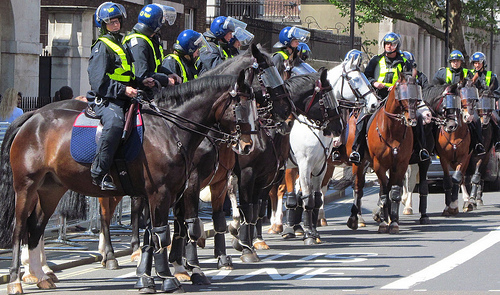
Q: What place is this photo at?
A: It is at the street.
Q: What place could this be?
A: It is a street.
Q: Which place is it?
A: It is a street.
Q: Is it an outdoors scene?
A: Yes, it is outdoors.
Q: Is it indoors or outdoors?
A: It is outdoors.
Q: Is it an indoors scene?
A: No, it is outdoors.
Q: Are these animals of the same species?
A: Yes, all the animals are horses.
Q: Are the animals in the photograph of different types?
A: No, all the animals are horses.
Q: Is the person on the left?
A: Yes, the person is on the left of the image.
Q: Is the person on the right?
A: No, the person is on the left of the image.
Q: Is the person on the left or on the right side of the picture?
A: The person is on the left of the image.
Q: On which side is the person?
A: The person is on the left of the image.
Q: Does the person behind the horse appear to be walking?
A: Yes, the person is walking.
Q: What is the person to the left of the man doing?
A: The person is walking.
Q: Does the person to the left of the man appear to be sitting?
A: No, the person is walking.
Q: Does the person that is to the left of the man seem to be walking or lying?
A: The person is walking.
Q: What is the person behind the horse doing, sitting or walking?
A: The person is walking.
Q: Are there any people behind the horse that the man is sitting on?
A: Yes, there is a person behind the horse.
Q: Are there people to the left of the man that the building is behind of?
A: Yes, there is a person to the left of the man.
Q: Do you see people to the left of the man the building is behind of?
A: Yes, there is a person to the left of the man.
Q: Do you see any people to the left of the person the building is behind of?
A: Yes, there is a person to the left of the man.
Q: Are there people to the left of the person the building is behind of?
A: Yes, there is a person to the left of the man.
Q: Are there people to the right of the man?
A: No, the person is to the left of the man.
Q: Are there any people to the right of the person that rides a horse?
A: No, the person is to the left of the man.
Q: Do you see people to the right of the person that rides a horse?
A: No, the person is to the left of the man.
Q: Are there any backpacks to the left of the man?
A: No, there is a person to the left of the man.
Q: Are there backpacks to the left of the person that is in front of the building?
A: No, there is a person to the left of the man.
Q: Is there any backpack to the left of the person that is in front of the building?
A: No, there is a person to the left of the man.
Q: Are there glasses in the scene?
A: No, there are no glasses.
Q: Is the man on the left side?
A: Yes, the man is on the left of the image.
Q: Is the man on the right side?
A: No, the man is on the left of the image.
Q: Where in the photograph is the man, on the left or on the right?
A: The man is on the left of the image.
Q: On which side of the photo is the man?
A: The man is on the left of the image.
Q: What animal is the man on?
A: The man is on the horse.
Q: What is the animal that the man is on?
A: The animal is a horse.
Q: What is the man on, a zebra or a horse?
A: The man is on a horse.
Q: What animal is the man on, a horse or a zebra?
A: The man is on a horse.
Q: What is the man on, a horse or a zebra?
A: The man is on a horse.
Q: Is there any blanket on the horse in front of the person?
A: No, there is a man on the horse.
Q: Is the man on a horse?
A: Yes, the man is on a horse.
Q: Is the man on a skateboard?
A: No, the man is on a horse.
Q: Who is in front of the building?
A: The man is in front of the building.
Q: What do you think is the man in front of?
A: The man is in front of the building.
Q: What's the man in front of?
A: The man is in front of the building.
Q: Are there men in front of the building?
A: Yes, there is a man in front of the building.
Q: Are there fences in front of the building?
A: No, there is a man in front of the building.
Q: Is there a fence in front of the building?
A: No, there is a man in front of the building.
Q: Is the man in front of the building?
A: Yes, the man is in front of the building.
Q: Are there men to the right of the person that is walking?
A: Yes, there is a man to the right of the person.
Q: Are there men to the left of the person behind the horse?
A: No, the man is to the right of the person.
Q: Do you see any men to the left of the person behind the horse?
A: No, the man is to the right of the person.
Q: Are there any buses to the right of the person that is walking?
A: No, there is a man to the right of the person.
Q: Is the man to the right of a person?
A: Yes, the man is to the right of a person.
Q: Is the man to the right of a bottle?
A: No, the man is to the right of a person.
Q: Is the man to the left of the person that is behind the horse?
A: No, the man is to the right of the person.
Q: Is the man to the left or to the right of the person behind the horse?
A: The man is to the right of the person.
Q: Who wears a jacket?
A: The man wears a jacket.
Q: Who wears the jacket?
A: The man wears a jacket.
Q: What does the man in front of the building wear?
A: The man wears a jacket.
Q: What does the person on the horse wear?
A: The man wears a jacket.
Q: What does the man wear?
A: The man wears a jacket.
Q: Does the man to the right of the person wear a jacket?
A: Yes, the man wears a jacket.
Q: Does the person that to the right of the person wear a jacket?
A: Yes, the man wears a jacket.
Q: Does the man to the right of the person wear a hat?
A: No, the man wears a jacket.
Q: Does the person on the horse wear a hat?
A: No, the man wears a jacket.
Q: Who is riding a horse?
A: The man is riding a horse.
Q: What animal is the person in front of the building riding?
A: The man is riding a horse.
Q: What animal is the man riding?
A: The man is riding a horse.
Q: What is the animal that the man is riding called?
A: The animal is a horse.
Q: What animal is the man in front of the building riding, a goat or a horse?
A: The man is riding a horse.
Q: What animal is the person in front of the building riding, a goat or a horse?
A: The man is riding a horse.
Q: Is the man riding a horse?
A: Yes, the man is riding a horse.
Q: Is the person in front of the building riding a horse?
A: Yes, the man is riding a horse.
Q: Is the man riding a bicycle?
A: No, the man is riding a horse.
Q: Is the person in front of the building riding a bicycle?
A: No, the man is riding a horse.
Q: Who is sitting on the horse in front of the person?
A: The man is sitting on the horse.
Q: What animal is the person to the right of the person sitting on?
A: The man is sitting on the horse.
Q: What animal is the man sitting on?
A: The man is sitting on the horse.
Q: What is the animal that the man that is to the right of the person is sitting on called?
A: The animal is a horse.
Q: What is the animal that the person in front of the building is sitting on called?
A: The animal is a horse.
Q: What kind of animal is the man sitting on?
A: The man is sitting on the horse.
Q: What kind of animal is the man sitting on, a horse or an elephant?
A: The man is sitting on a horse.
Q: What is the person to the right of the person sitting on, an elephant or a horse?
A: The man is sitting on a horse.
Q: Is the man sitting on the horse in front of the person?
A: Yes, the man is sitting on the horse.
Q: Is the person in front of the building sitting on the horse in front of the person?
A: Yes, the man is sitting on the horse.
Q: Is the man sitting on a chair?
A: No, the man is sitting on the horse.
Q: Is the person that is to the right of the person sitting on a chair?
A: No, the man is sitting on the horse.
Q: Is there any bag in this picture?
A: No, there are no bags.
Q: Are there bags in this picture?
A: No, there are no bags.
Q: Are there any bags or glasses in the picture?
A: No, there are no bags or glasses.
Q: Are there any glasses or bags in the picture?
A: No, there are no bags or glasses.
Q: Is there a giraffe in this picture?
A: No, there are no giraffes.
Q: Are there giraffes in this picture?
A: No, there are no giraffes.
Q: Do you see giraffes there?
A: No, there are no giraffes.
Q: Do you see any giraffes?
A: No, there are no giraffes.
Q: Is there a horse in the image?
A: Yes, there is a horse.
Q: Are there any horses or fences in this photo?
A: Yes, there is a horse.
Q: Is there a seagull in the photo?
A: No, there are no seagulls.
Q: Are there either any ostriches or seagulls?
A: No, there are no seagulls or ostriches.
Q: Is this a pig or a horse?
A: This is a horse.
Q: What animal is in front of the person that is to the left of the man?
A: The horse is in front of the person.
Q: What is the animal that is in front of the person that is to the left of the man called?
A: The animal is a horse.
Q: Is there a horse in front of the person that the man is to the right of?
A: Yes, there is a horse in front of the person.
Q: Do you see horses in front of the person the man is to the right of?
A: Yes, there is a horse in front of the person.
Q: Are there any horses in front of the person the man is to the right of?
A: Yes, there is a horse in front of the person.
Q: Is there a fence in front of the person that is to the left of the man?
A: No, there is a horse in front of the person.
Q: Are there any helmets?
A: Yes, there is a helmet.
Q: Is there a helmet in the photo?
A: Yes, there is a helmet.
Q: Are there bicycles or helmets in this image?
A: Yes, there is a helmet.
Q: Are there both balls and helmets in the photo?
A: No, there is a helmet but no balls.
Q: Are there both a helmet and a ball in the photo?
A: No, there is a helmet but no balls.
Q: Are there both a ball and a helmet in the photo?
A: No, there is a helmet but no balls.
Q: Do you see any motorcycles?
A: No, there are no motorcycles.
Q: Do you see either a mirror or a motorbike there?
A: No, there are no motorcycles or mirrors.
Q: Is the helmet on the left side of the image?
A: Yes, the helmet is on the left of the image.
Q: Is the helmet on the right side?
A: No, the helmet is on the left of the image.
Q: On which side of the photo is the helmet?
A: The helmet is on the left of the image.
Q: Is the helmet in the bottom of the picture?
A: No, the helmet is in the top of the image.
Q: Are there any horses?
A: Yes, there is a horse.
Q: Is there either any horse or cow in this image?
A: Yes, there is a horse.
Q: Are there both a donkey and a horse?
A: No, there is a horse but no donkeys.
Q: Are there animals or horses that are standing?
A: Yes, the horse is standing.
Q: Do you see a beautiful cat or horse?
A: Yes, there is a beautiful horse.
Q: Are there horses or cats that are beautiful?
A: Yes, the horse is beautiful.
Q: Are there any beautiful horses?
A: Yes, there is a beautiful horse.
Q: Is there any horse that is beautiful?
A: Yes, there is a horse that is beautiful.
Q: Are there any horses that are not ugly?
A: Yes, there is an beautiful horse.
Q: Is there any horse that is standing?
A: Yes, there is a horse that is standing.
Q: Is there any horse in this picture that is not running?
A: Yes, there is a horse that is standing.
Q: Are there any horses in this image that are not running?
A: Yes, there is a horse that is standing.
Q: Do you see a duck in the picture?
A: No, there are no ducks.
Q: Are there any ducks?
A: No, there are no ducks.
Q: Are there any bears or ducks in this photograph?
A: No, there are no ducks or bears.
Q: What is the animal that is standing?
A: The animal is a horse.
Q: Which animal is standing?
A: The animal is a horse.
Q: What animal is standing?
A: The animal is a horse.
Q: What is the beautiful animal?
A: The animal is a horse.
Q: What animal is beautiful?
A: The animal is a horse.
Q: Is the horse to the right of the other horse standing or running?
A: The horse is standing.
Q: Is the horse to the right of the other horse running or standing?
A: The horse is standing.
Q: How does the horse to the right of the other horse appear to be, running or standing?
A: The horse is standing.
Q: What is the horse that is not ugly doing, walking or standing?
A: The horse is standing.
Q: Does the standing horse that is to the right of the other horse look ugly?
A: No, the horse is beautiful.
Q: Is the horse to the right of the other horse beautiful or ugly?
A: The horse is beautiful.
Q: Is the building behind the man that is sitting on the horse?
A: Yes, the building is behind the man.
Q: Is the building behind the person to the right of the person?
A: Yes, the building is behind the man.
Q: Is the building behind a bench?
A: No, the building is behind the man.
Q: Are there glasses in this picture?
A: No, there are no glasses.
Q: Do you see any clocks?
A: No, there are no clocks.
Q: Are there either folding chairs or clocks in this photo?
A: No, there are no clocks or folding chairs.